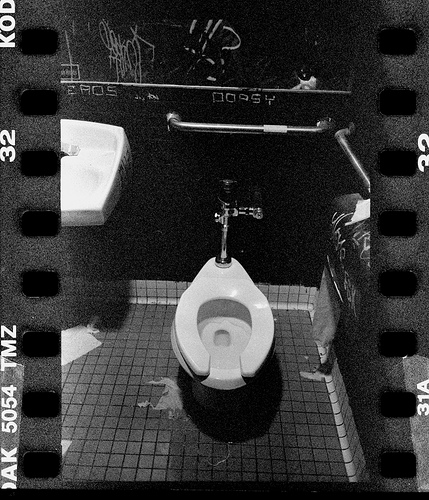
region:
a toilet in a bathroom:
[169, 249, 279, 395]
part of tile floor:
[283, 413, 339, 474]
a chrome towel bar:
[150, 98, 340, 157]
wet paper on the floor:
[120, 366, 190, 443]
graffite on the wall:
[68, 11, 329, 92]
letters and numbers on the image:
[0, 5, 33, 495]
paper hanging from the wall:
[291, 244, 358, 369]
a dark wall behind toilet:
[138, 133, 318, 266]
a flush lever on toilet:
[208, 197, 236, 236]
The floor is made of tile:
[95, 418, 335, 474]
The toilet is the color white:
[168, 250, 278, 416]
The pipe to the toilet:
[209, 173, 273, 272]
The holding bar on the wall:
[157, 103, 338, 144]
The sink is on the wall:
[59, 109, 131, 229]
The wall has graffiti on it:
[75, 14, 305, 109]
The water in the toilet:
[199, 314, 249, 359]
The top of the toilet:
[171, 274, 273, 383]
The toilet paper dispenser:
[303, 191, 386, 373]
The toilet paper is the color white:
[309, 262, 344, 368]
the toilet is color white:
[167, 255, 279, 402]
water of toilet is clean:
[198, 309, 250, 361]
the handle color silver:
[159, 111, 329, 144]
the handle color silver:
[330, 125, 375, 199]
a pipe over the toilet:
[200, 176, 267, 267]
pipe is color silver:
[201, 172, 270, 271]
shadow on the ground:
[177, 395, 290, 451]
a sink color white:
[63, 117, 138, 232]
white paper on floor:
[131, 367, 199, 440]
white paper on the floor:
[61, 319, 105, 365]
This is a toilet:
[146, 224, 310, 455]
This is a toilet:
[166, 222, 296, 454]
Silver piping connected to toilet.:
[201, 176, 264, 258]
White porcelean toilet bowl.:
[168, 254, 277, 393]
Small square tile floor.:
[105, 437, 149, 465]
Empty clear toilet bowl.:
[168, 262, 280, 391]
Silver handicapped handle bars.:
[167, 109, 328, 139]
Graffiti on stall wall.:
[91, 18, 174, 81]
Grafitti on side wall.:
[324, 213, 374, 298]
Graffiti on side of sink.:
[69, 114, 133, 228]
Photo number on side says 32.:
[0, 128, 20, 165]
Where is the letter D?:
[201, 84, 283, 113]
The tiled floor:
[11, 283, 348, 487]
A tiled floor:
[8, 291, 345, 483]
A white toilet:
[165, 258, 276, 394]